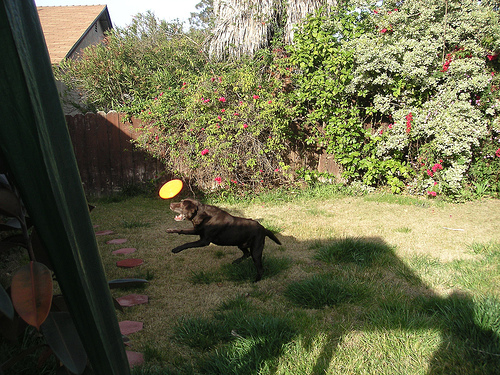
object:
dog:
[165, 196, 280, 284]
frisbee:
[159, 178, 184, 198]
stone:
[116, 258, 143, 268]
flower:
[201, 149, 208, 156]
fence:
[79, 99, 396, 174]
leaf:
[10, 256, 55, 329]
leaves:
[313, 50, 330, 61]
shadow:
[428, 287, 498, 371]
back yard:
[8, 83, 498, 374]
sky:
[115, 1, 210, 34]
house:
[33, 0, 117, 103]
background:
[44, 0, 483, 70]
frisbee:
[116, 258, 143, 268]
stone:
[110, 275, 152, 290]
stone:
[114, 292, 149, 310]